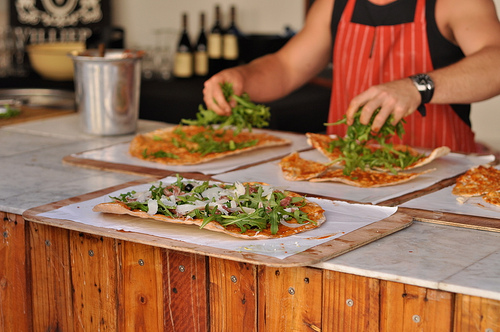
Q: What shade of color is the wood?
A: Brown.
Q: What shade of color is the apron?
A: Red.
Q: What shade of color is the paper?
A: White.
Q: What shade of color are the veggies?
A: Green.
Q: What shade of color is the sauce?
A: Red.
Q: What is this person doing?
A: Cocking.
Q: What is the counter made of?
A: Wood.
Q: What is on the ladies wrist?
A: A watch.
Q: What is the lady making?
A: A pizza.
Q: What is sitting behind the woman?
A: Bottles of wine.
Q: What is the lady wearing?
A: A red apron.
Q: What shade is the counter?
A: White.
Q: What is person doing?
A: Making food.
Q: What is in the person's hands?
A: Lettuce.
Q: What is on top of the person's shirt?
A: An apron.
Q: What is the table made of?
A: Wood.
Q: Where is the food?
A: On serving trays.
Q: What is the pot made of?
A: Metal.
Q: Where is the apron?
A: On the cook.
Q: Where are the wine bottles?
A: Along the back wall.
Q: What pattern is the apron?
A: Striped.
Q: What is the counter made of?
A: Stone and wood.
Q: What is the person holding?
A: Greens.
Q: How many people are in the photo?
A: One.